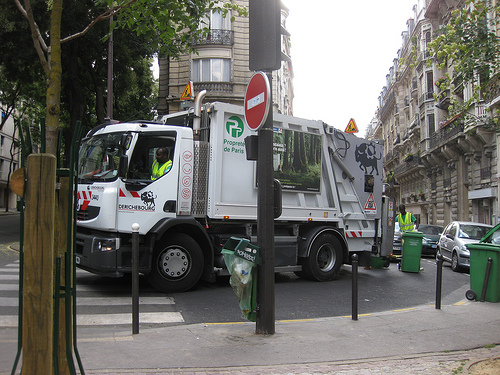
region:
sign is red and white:
[236, 72, 297, 142]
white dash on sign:
[240, 91, 267, 123]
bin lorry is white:
[52, 111, 389, 243]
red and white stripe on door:
[103, 178, 152, 211]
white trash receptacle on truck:
[216, 87, 428, 278]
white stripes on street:
[4, 255, 178, 353]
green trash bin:
[399, 218, 422, 298]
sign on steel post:
[215, 9, 295, 339]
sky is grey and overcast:
[287, 15, 392, 123]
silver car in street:
[410, 232, 487, 289]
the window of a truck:
[121, 129, 179, 195]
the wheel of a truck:
[296, 225, 351, 282]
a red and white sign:
[238, 65, 275, 136]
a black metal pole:
[241, 2, 285, 341]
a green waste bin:
[394, 225, 430, 280]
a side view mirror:
[113, 143, 137, 185]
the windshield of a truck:
[71, 124, 139, 184]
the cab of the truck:
[66, 106, 199, 274]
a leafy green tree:
[0, 2, 252, 162]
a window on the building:
[187, 50, 237, 87]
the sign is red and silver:
[237, 65, 298, 149]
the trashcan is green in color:
[396, 228, 432, 283]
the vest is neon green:
[395, 206, 427, 227]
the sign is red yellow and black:
[171, 75, 211, 110]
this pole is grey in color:
[126, 255, 148, 326]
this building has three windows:
[415, 19, 452, 159]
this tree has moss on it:
[39, 1, 74, 142]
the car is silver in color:
[431, 205, 492, 282]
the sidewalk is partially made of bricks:
[347, 360, 424, 373]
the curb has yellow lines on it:
[276, 311, 327, 331]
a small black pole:
[332, 248, 373, 342]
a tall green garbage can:
[388, 223, 428, 289]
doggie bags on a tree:
[204, 225, 274, 344]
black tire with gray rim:
[124, 237, 205, 327]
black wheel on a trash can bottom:
[444, 267, 486, 319]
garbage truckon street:
[7, 120, 383, 321]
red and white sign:
[349, 194, 376, 237]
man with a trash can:
[351, 197, 450, 295]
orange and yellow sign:
[172, 72, 214, 109]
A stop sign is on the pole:
[242, 74, 270, 129]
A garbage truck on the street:
[72, 103, 389, 283]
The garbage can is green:
[399, 230, 422, 275]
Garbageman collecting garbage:
[395, 201, 429, 277]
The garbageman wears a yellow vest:
[398, 212, 414, 230]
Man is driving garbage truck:
[150, 145, 172, 182]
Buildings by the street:
[374, 0, 495, 233]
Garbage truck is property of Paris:
[221, 115, 248, 160]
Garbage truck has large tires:
[147, 227, 209, 292]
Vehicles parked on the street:
[390, 211, 482, 273]